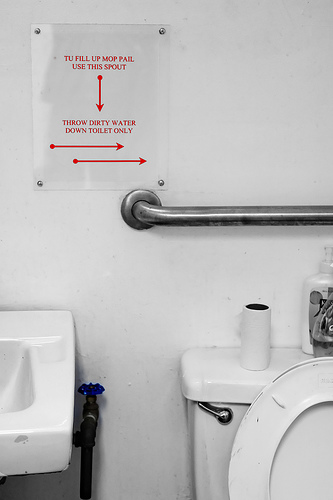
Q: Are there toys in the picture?
A: No, there are no toys.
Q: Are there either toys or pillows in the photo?
A: No, there are no toys or pillows.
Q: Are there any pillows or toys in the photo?
A: No, there are no toys or pillows.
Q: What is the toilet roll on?
A: The toilet roll is on the toilet.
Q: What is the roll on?
A: The toilet roll is on the toilet.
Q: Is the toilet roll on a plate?
A: No, the toilet roll is on a toilet.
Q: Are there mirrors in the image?
A: No, there are no mirrors.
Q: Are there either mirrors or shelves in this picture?
A: No, there are no mirrors or shelves.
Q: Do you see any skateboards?
A: No, there are no skateboards.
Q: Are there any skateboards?
A: No, there are no skateboards.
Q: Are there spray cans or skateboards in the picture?
A: No, there are no skateboards or spray cans.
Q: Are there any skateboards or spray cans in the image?
A: No, there are no skateboards or spray cans.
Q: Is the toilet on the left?
A: No, the toilet is on the right of the image.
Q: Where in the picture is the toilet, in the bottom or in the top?
A: The toilet is in the bottom of the image.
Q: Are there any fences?
A: No, there are no fences.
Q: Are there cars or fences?
A: No, there are no fences or cars.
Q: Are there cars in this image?
A: No, there are no cars.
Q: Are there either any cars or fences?
A: No, there are no cars or fences.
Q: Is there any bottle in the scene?
A: Yes, there is a bottle.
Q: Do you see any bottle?
A: Yes, there is a bottle.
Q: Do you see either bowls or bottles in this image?
A: Yes, there is a bottle.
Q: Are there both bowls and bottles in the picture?
A: No, there is a bottle but no bowls.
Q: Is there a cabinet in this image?
A: No, there are no cabinets.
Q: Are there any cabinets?
A: No, there are no cabinets.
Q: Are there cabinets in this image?
A: No, there are no cabinets.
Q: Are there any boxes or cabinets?
A: No, there are no cabinets or boxes.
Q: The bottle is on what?
A: The bottle is on the toilet.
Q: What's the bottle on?
A: The bottle is on the toilet.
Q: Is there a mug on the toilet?
A: No, there is a bottle on the toilet.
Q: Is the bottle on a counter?
A: No, the bottle is on the toilet.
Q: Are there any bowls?
A: No, there are no bowls.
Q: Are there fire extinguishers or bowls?
A: No, there are no bowls or fire extinguishers.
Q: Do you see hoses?
A: No, there are no hoses.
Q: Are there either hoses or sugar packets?
A: No, there are no hoses or sugar packets.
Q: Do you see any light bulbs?
A: No, there are no light bulbs.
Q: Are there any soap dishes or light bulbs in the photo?
A: No, there are no light bulbs or soap dishes.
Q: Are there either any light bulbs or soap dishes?
A: No, there are no light bulbs or soap dishes.